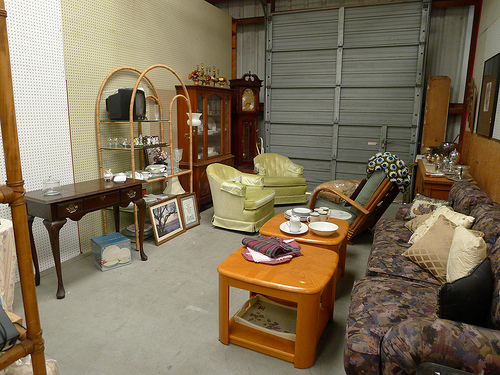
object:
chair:
[253, 153, 307, 205]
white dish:
[280, 221, 309, 236]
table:
[216, 243, 339, 369]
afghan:
[365, 151, 412, 193]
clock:
[229, 71, 264, 171]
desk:
[23, 176, 147, 300]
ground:
[434, 127, 464, 177]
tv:
[105, 88, 146, 122]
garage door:
[264, 0, 433, 204]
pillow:
[445, 225, 487, 284]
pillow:
[435, 256, 494, 327]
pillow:
[401, 214, 485, 285]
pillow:
[408, 207, 476, 245]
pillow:
[405, 211, 436, 234]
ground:
[9, 204, 401, 375]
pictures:
[148, 197, 186, 247]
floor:
[10, 207, 372, 375]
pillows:
[402, 192, 450, 222]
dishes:
[279, 206, 340, 236]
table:
[258, 212, 349, 277]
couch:
[342, 181, 499, 375]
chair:
[306, 170, 412, 246]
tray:
[233, 294, 297, 342]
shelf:
[94, 64, 193, 251]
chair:
[206, 163, 276, 233]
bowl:
[308, 222, 339, 237]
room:
[0, 0, 499, 375]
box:
[91, 232, 132, 272]